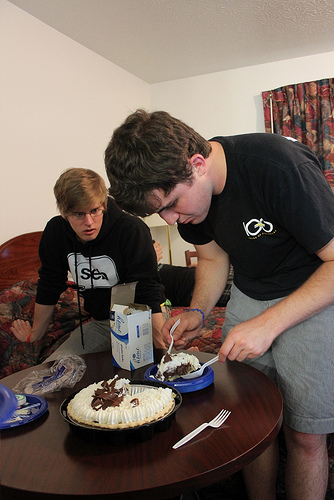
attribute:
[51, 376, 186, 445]
pie — cut, white, black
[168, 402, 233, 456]
fork — white, plastic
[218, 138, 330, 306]
shirt — black, short sleeved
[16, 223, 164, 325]
sweatshirt — black, long sleeved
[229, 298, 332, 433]
shorts — gray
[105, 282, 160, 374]
box — white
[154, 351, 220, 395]
plates — blue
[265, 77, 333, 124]
curtain — multi-colored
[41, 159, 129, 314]
boy — blonde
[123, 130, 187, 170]
hair — brown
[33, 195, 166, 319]
shirt — black, white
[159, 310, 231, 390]
forks — plastic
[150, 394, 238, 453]
forks — plastic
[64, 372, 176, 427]
cake — white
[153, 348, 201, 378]
cake — white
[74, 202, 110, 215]
glasses — pair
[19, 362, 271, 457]
table — brown, wooden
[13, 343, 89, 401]
bags — plastic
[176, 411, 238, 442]
fork — plastic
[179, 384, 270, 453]
table — round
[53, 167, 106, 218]
hair — blonde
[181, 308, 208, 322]
bracelet — blue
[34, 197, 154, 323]
hoodie — black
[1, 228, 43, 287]
cot — brown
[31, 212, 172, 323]
jacket — black and white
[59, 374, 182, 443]
pie — chocolate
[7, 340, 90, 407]
bag — plastic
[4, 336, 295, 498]
table — dark, wooden, round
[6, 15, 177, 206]
wall — white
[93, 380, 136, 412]
curls — chocolate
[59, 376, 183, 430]
pie — cream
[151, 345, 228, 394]
paper plates — blue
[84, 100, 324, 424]
man — young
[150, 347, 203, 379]
pie — CREAM 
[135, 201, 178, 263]
lamp — white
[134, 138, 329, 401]
man — young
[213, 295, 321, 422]
shorts — gray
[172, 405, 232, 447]
fork — white, plastic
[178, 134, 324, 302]
shirt — black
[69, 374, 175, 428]
pie — chocolate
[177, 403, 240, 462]
forks — plastic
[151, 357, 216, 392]
plate — blue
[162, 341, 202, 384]
pie — chocolate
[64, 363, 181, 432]
pie — chocolate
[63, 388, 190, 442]
container — black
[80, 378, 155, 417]
whipped cream — white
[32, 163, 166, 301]
man — young